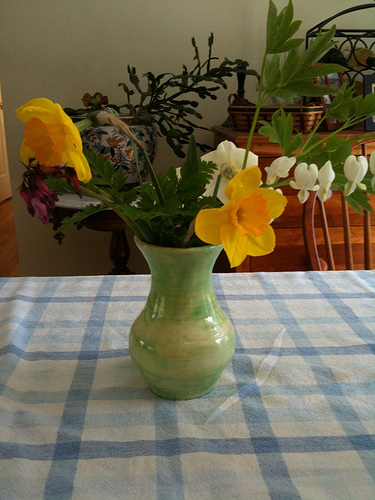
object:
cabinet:
[209, 124, 375, 273]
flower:
[194, 165, 288, 269]